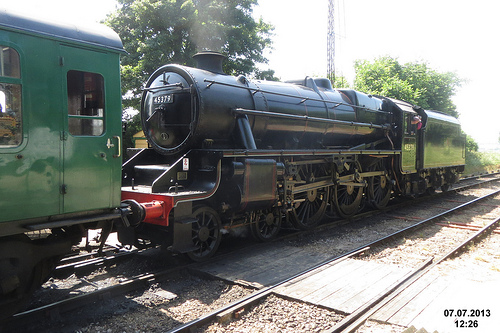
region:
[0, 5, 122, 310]
A green train car.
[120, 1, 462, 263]
A black train engine.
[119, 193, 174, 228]
The train connector area is painted red.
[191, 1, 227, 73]
The engine is pouring out smoke.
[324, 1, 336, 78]
A radio tower.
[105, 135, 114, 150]
Door handle of the train car.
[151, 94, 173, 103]
The number 45379 is on the front of the train..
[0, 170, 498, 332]
A long train track.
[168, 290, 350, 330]
Gravel is between the train tracks.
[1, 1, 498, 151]
It is very bright and sunny.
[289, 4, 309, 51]
this is the sky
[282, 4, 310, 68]
the sky is bright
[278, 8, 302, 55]
the sky is full of clouds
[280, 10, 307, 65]
the clouds are white in color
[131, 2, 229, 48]
this is a tree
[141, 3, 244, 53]
the leaves are green in color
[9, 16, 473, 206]
this is a train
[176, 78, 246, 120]
the part is black in color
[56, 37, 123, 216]
this is a door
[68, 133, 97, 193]
the door is green in color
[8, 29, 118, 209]
train car is green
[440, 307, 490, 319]
date on photograph in corner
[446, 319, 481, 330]
time photo was taken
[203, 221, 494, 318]
three train tracks displayed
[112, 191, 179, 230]
hookup for train is in red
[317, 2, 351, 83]
electric tower in background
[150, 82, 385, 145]
train car is black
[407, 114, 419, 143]
conducter sticking his head out of window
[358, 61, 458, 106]
trees in back are green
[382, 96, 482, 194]
engine is in back of train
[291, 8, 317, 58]
the sky is bright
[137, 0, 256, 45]
the tree is tall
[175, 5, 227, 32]
the leaves are green in color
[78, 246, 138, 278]
this is a railway line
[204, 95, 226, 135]
the train is black in color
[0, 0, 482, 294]
a locomotive on a railroad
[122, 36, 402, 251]
engine of locomotive is black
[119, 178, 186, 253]
couplers of locomotive are red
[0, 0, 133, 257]
passenger car of locomotive is green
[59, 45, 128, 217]
door of locomotive is green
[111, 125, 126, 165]
silver handle of door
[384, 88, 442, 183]
person behind engine of locomotive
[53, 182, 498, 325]
railroad of train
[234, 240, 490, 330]
part of railroad covered with planks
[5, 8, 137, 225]
roof of car is black